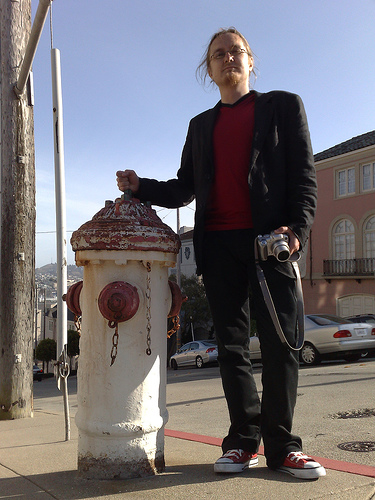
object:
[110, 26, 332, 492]
man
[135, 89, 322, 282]
coat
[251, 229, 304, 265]
camera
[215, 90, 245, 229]
shirt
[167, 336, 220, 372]
cars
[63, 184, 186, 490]
hydrant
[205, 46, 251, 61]
eyeglasses